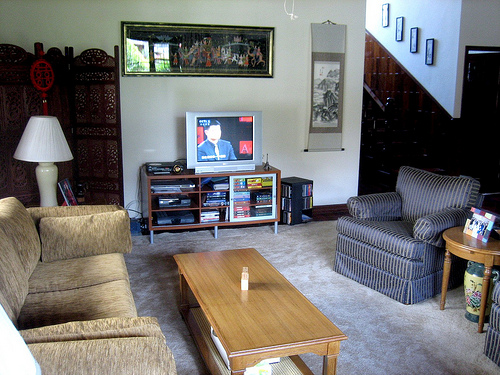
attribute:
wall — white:
[111, 4, 313, 194]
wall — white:
[380, 8, 476, 116]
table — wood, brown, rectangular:
[180, 245, 342, 353]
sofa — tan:
[15, 193, 164, 374]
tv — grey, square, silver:
[193, 117, 262, 173]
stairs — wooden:
[364, 74, 421, 176]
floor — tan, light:
[282, 234, 396, 350]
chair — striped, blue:
[385, 149, 443, 289]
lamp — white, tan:
[22, 100, 78, 212]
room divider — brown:
[16, 37, 111, 114]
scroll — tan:
[320, 29, 346, 130]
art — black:
[117, 11, 275, 80]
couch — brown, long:
[21, 213, 115, 354]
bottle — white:
[234, 263, 255, 294]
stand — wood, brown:
[140, 159, 281, 222]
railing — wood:
[365, 89, 398, 125]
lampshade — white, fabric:
[22, 110, 69, 151]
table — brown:
[455, 223, 498, 300]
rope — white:
[276, 3, 296, 31]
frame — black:
[120, 23, 127, 72]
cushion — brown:
[43, 211, 142, 244]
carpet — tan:
[138, 240, 185, 346]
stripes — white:
[412, 178, 448, 192]